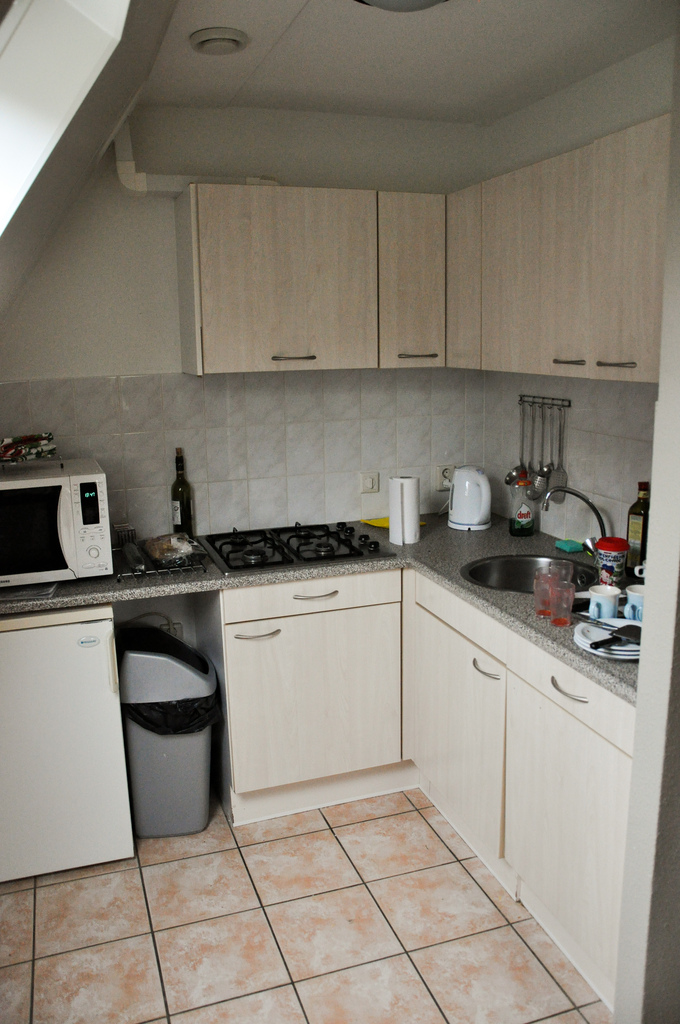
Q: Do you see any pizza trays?
A: No, there are no pizza trays.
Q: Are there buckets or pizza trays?
A: No, there are no pizza trays or buckets.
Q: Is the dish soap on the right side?
A: Yes, the dish soap is on the right of the image.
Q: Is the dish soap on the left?
A: No, the dish soap is on the right of the image.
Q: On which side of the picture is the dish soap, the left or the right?
A: The dish soap is on the right of the image.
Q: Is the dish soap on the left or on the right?
A: The dish soap is on the right of the image.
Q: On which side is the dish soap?
A: The dish soap is on the right of the image.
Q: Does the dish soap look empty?
A: Yes, the dish soap is empty.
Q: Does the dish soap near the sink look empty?
A: Yes, the dish soap is empty.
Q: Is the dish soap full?
A: No, the dish soap is empty.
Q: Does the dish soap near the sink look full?
A: No, the dish soap is empty.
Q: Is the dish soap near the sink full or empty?
A: The dish soap is empty.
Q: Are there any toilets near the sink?
A: No, there is a dish soap near the sink.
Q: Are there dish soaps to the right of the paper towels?
A: Yes, there is a dish soap to the right of the paper towels.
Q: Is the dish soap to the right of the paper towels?
A: Yes, the dish soap is to the right of the paper towels.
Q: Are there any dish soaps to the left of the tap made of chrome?
A: Yes, there is a dish soap to the left of the faucet.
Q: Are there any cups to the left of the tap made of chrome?
A: No, there is a dish soap to the left of the tap.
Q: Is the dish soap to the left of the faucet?
A: Yes, the dish soap is to the left of the faucet.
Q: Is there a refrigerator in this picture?
A: Yes, there is a refrigerator.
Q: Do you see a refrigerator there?
A: Yes, there is a refrigerator.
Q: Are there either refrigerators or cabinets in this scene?
A: Yes, there is a refrigerator.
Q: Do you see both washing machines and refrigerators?
A: No, there is a refrigerator but no washing machines.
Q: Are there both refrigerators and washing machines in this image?
A: No, there is a refrigerator but no washing machines.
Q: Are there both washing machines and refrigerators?
A: No, there is a refrigerator but no washing machines.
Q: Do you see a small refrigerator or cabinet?
A: Yes, there is a small refrigerator.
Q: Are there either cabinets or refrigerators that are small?
A: Yes, the refrigerator is small.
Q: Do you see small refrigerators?
A: Yes, there is a small refrigerator.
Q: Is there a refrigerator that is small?
A: Yes, there is a refrigerator that is small.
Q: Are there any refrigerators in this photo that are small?
A: Yes, there is a refrigerator that is small.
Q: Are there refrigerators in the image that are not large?
A: Yes, there is a small refrigerator.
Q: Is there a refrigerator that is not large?
A: Yes, there is a small refrigerator.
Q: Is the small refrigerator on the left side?
A: Yes, the refrigerator is on the left of the image.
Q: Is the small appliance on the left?
A: Yes, the refrigerator is on the left of the image.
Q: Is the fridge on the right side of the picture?
A: No, the fridge is on the left of the image.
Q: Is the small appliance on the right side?
A: No, the fridge is on the left of the image.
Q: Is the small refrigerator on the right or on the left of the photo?
A: The fridge is on the left of the image.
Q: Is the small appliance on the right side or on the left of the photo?
A: The fridge is on the left of the image.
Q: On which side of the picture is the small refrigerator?
A: The fridge is on the left of the image.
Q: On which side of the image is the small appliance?
A: The fridge is on the left of the image.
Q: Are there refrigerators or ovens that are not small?
A: No, there is a refrigerator but it is small.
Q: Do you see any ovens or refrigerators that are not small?
A: No, there is a refrigerator but it is small.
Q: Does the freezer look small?
A: Yes, the freezer is small.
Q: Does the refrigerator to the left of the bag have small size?
A: Yes, the fridge is small.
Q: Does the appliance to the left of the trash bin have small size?
A: Yes, the fridge is small.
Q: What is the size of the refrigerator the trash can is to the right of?
A: The refrigerator is small.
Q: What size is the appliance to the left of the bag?
A: The refrigerator is small.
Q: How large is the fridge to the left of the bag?
A: The refrigerator is small.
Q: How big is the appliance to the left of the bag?
A: The refrigerator is small.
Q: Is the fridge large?
A: No, the fridge is small.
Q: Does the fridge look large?
A: No, the fridge is small.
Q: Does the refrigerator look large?
A: No, the refrigerator is small.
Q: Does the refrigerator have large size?
A: No, the refrigerator is small.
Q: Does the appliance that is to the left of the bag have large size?
A: No, the refrigerator is small.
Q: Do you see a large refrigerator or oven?
A: No, there is a refrigerator but it is small.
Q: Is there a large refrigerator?
A: No, there is a refrigerator but it is small.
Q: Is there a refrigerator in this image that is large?
A: No, there is a refrigerator but it is small.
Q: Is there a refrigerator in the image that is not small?
A: No, there is a refrigerator but it is small.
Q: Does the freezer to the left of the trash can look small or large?
A: The fridge is small.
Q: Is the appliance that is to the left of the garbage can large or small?
A: The fridge is small.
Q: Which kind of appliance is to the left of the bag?
A: The appliance is a refrigerator.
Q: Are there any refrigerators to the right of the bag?
A: No, the refrigerator is to the left of the bag.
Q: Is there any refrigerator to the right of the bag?
A: No, the refrigerator is to the left of the bag.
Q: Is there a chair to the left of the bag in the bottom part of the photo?
A: No, there is a refrigerator to the left of the bag.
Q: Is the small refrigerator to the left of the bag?
A: Yes, the refrigerator is to the left of the bag.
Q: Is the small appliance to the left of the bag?
A: Yes, the refrigerator is to the left of the bag.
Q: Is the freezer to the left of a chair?
A: No, the freezer is to the left of the bag.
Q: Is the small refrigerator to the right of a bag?
A: No, the refrigerator is to the left of a bag.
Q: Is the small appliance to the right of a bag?
A: No, the refrigerator is to the left of a bag.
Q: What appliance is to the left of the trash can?
A: The appliance is a refrigerator.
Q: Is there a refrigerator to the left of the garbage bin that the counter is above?
A: Yes, there is a refrigerator to the left of the garbage bin.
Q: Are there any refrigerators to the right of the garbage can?
A: No, the refrigerator is to the left of the garbage can.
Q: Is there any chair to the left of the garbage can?
A: No, there is a refrigerator to the left of the garbage can.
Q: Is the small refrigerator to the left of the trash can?
A: Yes, the refrigerator is to the left of the trash can.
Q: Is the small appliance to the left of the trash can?
A: Yes, the refrigerator is to the left of the trash can.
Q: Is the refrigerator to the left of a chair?
A: No, the refrigerator is to the left of the trash can.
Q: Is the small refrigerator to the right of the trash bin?
A: No, the freezer is to the left of the trash bin.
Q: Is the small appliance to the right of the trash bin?
A: No, the freezer is to the left of the trash bin.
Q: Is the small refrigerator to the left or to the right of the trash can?
A: The freezer is to the left of the trash can.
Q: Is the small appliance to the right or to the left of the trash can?
A: The freezer is to the left of the trash can.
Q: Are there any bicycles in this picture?
A: No, there are no bicycles.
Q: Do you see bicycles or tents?
A: No, there are no bicycles or tents.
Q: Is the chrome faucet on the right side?
A: Yes, the faucet is on the right of the image.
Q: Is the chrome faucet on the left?
A: No, the faucet is on the right of the image.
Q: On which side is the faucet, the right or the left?
A: The faucet is on the right of the image.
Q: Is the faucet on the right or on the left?
A: The faucet is on the right of the image.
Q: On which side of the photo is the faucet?
A: The faucet is on the right of the image.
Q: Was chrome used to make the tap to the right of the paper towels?
A: Yes, the tap is made of chrome.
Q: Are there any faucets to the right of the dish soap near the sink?
A: Yes, there is a faucet to the right of the dish soap.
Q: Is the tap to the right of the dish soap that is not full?
A: Yes, the tap is to the right of the dish soap.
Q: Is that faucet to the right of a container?
A: No, the faucet is to the right of the dish soap.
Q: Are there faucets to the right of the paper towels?
A: Yes, there is a faucet to the right of the paper towels.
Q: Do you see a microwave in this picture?
A: Yes, there is a microwave.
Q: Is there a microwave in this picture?
A: Yes, there is a microwave.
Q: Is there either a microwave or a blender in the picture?
A: Yes, there is a microwave.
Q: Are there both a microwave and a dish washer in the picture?
A: No, there is a microwave but no dishwashers.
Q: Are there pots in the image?
A: No, there are no pots.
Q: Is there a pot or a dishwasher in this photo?
A: No, there are no pots or dishwashers.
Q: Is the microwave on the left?
A: Yes, the microwave is on the left of the image.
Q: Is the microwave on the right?
A: No, the microwave is on the left of the image.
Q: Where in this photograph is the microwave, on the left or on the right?
A: The microwave is on the left of the image.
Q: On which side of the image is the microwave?
A: The microwave is on the left of the image.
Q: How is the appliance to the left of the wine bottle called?
A: The appliance is a microwave.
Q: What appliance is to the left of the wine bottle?
A: The appliance is a microwave.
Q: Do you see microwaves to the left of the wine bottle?
A: Yes, there is a microwave to the left of the wine bottle.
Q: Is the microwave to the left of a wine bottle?
A: Yes, the microwave is to the left of a wine bottle.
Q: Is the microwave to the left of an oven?
A: No, the microwave is to the left of a wine bottle.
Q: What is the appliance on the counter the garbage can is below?
A: The appliance is a microwave.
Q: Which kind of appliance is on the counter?
A: The appliance is a microwave.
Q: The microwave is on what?
A: The microwave is on the counter.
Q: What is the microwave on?
A: The microwave is on the counter.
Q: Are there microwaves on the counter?
A: Yes, there is a microwave on the counter.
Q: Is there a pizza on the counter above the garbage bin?
A: No, there is a microwave on the counter.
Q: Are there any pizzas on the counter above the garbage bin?
A: No, there is a microwave on the counter.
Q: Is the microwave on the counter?
A: Yes, the microwave is on the counter.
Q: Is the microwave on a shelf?
A: No, the microwave is on the counter.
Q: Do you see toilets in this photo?
A: No, there are no toilets.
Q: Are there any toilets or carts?
A: No, there are no toilets or carts.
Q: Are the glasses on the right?
A: Yes, the glasses are on the right of the image.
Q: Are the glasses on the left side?
A: No, the glasses are on the right of the image.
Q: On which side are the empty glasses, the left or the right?
A: The glasses are on the right of the image.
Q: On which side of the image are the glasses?
A: The glasses are on the right of the image.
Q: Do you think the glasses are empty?
A: Yes, the glasses are empty.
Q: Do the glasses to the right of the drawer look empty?
A: Yes, the glasses are empty.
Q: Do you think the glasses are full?
A: No, the glasses are empty.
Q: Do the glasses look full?
A: No, the glasses are empty.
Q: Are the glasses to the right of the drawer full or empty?
A: The glasses are empty.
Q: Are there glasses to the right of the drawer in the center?
A: Yes, there are glasses to the right of the drawer.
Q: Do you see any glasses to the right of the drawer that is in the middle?
A: Yes, there are glasses to the right of the drawer.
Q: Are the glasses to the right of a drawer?
A: Yes, the glasses are to the right of a drawer.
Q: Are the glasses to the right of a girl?
A: No, the glasses are to the right of a drawer.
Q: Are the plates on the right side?
A: Yes, the plates are on the right of the image.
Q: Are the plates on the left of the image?
A: No, the plates are on the right of the image.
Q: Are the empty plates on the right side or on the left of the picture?
A: The plates are on the right of the image.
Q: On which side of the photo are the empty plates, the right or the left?
A: The plates are on the right of the image.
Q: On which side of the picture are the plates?
A: The plates are on the right of the image.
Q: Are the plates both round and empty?
A: Yes, the plates are round and empty.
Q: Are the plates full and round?
A: No, the plates are round but empty.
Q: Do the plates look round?
A: Yes, the plates are round.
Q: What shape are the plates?
A: The plates are round.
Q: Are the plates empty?
A: Yes, the plates are empty.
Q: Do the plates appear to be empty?
A: Yes, the plates are empty.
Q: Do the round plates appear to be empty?
A: Yes, the plates are empty.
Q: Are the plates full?
A: No, the plates are empty.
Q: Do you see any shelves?
A: No, there are no shelves.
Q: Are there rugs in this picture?
A: No, there are no rugs.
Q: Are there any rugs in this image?
A: No, there are no rugs.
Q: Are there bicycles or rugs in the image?
A: No, there are no rugs or bicycles.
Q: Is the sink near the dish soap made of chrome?
A: Yes, the sink is made of chrome.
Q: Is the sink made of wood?
A: No, the sink is made of chrome.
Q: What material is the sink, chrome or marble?
A: The sink is made of chrome.